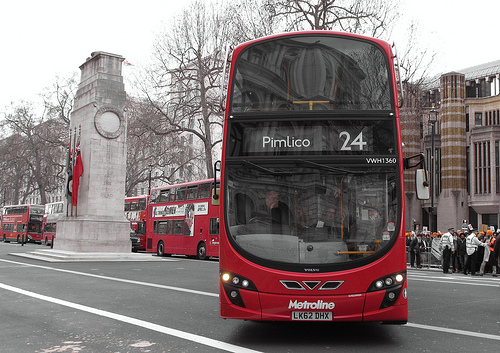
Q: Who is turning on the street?
A: A red bus.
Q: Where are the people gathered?
A: In front of the brown building.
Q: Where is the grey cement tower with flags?
A: In the middle of the street.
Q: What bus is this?
A: Red double decker bus.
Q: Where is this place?
A: In a city.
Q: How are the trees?
A: Have no leaves.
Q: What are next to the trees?
A: Buildings.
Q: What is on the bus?
A: A large windshield.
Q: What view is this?
A: A city street.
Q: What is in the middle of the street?
A: A monument.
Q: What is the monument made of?
A: Stone.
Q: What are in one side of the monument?
A: Three flags.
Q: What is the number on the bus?
A: 24.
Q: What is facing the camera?
A: A red bus.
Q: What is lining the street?
A: A row of busses.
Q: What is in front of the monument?
A: 3 flags.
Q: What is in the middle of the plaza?
A: A stone monument.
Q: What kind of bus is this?
A: A tourist bus.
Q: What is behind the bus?
A: A leafless tree.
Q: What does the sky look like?
A: Overcast.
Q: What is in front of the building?
A: A crowd of people.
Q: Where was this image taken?
A: In the street.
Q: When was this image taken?
A: In the morning.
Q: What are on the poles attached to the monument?
A: Flags.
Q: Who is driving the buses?
A: Bus drivers.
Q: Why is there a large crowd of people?
A: A rally is occurring.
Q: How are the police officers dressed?
A: In black pants and white shirts.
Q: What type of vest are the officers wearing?
A: Bulletproof vests.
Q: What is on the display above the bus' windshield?
A: The bus' route and number.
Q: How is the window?
A: Reflected.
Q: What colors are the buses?
A: Red and black.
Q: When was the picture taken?
A: During the day.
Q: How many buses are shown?
A: 5.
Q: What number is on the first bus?
A: 24.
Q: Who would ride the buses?
A: People.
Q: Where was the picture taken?
A: London.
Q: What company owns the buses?
A: Metroline.